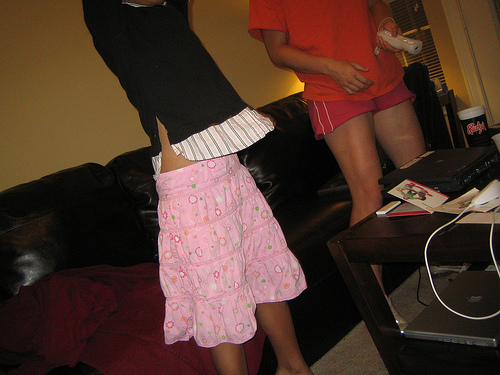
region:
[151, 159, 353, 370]
the skirt is pink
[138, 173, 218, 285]
the skirt is pink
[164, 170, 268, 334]
the skirt is pink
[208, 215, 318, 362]
the skirt is pink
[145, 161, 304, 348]
the pink skirt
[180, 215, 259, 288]
the pattern on the pink skirts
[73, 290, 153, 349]
the red fabric on the couch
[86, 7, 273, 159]
the black and white top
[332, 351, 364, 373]
the carpet on the ground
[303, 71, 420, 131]
the short red shorts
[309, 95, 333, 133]
the white stripes on the red shorts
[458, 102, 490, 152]
the cup on the table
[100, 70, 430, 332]
the black sofa behind the people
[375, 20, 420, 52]
the wii controller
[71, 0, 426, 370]
two girls standing up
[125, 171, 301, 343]
pink skirt on girl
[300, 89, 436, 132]
red shorts on girl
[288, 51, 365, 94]
right hand of girl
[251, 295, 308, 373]
left leg of girl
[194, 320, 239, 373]
right leg of girl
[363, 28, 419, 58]
wii control in girl's hand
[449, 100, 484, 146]
plastic cup on coffee table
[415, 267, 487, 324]
cord for device on table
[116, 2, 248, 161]
black shirt on girl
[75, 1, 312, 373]
The person in the pink skirt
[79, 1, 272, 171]
The black shirt of the person in a pink skirt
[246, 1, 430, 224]
The person in the red shorts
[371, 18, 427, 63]
The wii remote being held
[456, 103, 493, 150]
The black cup with red writing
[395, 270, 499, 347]
The silver apple laptop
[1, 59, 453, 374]
The couch behind the two people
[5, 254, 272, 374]
The red blanket on the couch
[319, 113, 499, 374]
The coffee table in front of the people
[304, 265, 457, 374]
The exposed portion of carpet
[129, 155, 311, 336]
woman wearing a pink skirt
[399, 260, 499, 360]
a laptop with its lid down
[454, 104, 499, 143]
a plastic black cup with white edges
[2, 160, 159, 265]
a black leather couch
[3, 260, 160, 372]
red blanket on a couch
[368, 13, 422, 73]
man holding a gaming controller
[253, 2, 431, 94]
man wearing an orange shirt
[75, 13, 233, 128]
woman wearing a black shirt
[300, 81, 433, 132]
man wearing red shorts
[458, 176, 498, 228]
a white gaming controller